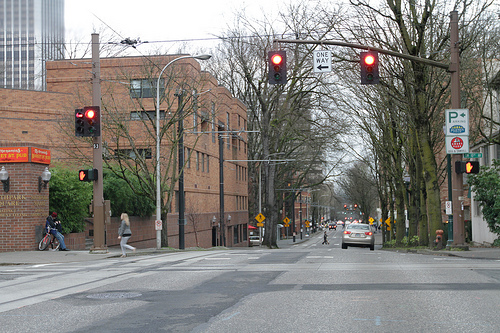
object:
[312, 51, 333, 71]
sign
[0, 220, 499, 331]
street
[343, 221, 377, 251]
car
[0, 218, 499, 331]
road